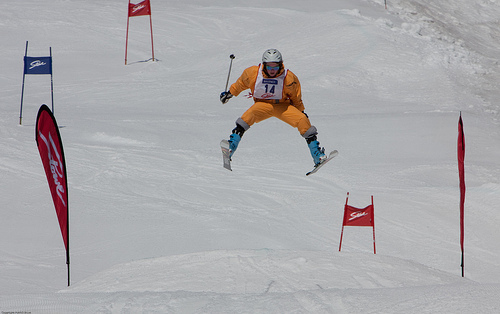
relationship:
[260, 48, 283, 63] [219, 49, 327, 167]
helmet on him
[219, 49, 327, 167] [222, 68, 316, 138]
him wearing snowsuit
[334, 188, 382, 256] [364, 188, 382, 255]
banner held up by stick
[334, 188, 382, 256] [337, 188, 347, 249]
banner held up by stick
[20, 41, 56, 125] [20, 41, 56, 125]
banner between banner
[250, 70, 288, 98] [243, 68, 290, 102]
14 on h chest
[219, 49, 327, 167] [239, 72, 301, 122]
him wearing a ski suit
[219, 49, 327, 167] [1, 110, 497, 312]
him jumping over snow hill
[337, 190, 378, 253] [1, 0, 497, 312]
banner in snow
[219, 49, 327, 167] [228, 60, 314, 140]
him skiing in a ski suit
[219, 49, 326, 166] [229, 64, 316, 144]
snowboarder wearing a ski suit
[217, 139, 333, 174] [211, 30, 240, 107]
snowboarder holding guide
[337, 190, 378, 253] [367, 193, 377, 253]
banner with stick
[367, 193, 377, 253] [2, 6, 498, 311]
stick in ground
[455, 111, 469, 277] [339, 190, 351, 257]
flag with stick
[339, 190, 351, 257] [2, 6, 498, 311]
stick in ground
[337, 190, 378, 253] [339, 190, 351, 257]
banner with stick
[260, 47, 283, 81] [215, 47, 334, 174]
helmet of snowboarder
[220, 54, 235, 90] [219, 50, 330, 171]
guide behind him